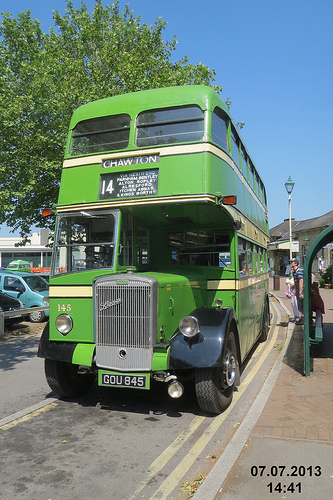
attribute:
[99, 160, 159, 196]
marquee — black, white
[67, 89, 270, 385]
bus — green, vintage, double decker, blue, headed to chawton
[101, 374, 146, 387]
license plate — black, white, gou845, number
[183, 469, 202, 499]
leaves — dead, pile, small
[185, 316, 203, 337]
headlight — shiny, round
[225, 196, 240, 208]
caution light — orange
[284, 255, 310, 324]
man — leaning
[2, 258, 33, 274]
van — green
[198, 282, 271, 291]
stripes — yellow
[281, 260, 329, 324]
people — standing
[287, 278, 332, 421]
sidewalk — flat bricks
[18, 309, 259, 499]
street — gray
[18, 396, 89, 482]
stains — oily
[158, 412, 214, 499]
lines — faded, yellow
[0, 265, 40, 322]
cars — parked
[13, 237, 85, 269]
building — white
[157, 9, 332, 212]
sky — deep blue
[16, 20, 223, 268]
trees — green, leafy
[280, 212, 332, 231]
roof — dark gray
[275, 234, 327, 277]
building — gray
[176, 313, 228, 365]
wheel cover — black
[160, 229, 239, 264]
window — recessed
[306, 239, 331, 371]
bus shelter — curved, bench, green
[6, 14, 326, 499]
photo — 2013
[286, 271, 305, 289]
shirt — blue, black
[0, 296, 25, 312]
car — blue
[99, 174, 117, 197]
number 14 — printed, white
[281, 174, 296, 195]
streetlamp — off